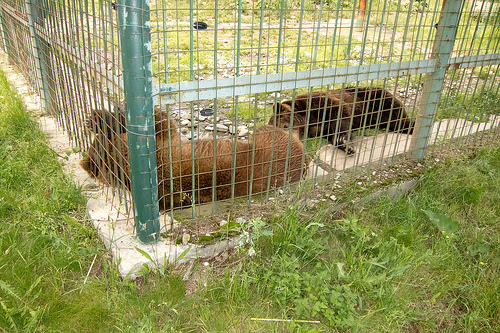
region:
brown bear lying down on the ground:
[266, 79, 417, 155]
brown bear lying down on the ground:
[73, 107, 319, 203]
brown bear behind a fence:
[262, 82, 414, 156]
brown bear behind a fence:
[77, 104, 319, 206]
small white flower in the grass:
[245, 243, 262, 258]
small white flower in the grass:
[215, 217, 232, 229]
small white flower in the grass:
[202, 258, 212, 270]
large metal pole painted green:
[114, 0, 159, 248]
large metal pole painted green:
[405, 2, 467, 174]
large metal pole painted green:
[30, 2, 54, 117]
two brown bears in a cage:
[51, 37, 437, 216]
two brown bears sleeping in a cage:
[64, 54, 457, 184]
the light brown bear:
[36, 89, 318, 214]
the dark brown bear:
[251, 68, 428, 163]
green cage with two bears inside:
[29, 9, 499, 237]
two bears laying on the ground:
[55, 53, 460, 217]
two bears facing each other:
[67, 57, 446, 207]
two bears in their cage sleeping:
[75, 65, 447, 206]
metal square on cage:
[214, 135, 236, 154]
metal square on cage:
[158, 194, 170, 211]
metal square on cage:
[171, 192, 194, 209]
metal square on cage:
[192, 188, 212, 203]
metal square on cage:
[212, 183, 231, 204]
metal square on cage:
[233, 180, 251, 196]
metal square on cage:
[251, 178, 269, 194]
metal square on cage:
[169, 160, 192, 174]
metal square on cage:
[193, 159, 213, 174]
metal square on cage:
[168, 128, 192, 145]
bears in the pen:
[54, 63, 388, 225]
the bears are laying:
[65, 53, 349, 208]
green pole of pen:
[90, 22, 161, 234]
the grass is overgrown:
[290, 228, 432, 319]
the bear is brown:
[216, 153, 258, 172]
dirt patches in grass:
[276, 13, 383, 58]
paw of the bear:
[333, 129, 356, 152]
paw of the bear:
[387, 116, 406, 128]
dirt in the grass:
[85, 265, 125, 310]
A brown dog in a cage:
[282, 69, 449, 149]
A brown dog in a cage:
[72, 84, 152, 209]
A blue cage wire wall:
[165, 44, 316, 248]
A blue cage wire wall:
[327, 12, 481, 169]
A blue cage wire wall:
[28, 12, 136, 204]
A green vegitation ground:
[325, 214, 479, 315]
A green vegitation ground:
[162, 239, 339, 319]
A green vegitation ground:
[5, 240, 155, 321]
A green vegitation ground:
[0, 92, 88, 293]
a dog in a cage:
[75, 75, 415, 264]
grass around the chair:
[385, 264, 435, 304]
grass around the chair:
[19, 136, 50, 207]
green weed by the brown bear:
[267, 248, 307, 301]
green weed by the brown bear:
[303, 256, 333, 319]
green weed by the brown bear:
[233, 251, 266, 286]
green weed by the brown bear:
[338, 211, 359, 251]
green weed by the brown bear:
[351, 250, 384, 283]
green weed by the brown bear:
[355, 260, 407, 298]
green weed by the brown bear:
[408, 206, 455, 241]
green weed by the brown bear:
[400, 195, 415, 247]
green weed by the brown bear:
[461, 170, 480, 212]